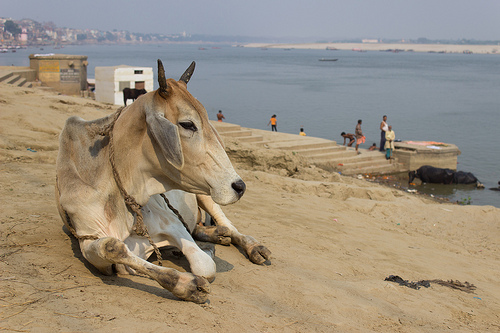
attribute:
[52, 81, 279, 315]
animal — laying, awake, lying down, lying, cow, tan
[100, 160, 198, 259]
rope — brown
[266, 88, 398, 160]
people — standing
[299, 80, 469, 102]
water — large body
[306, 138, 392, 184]
steps — stone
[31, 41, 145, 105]
group — buildings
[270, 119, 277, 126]
shirt — orange, pink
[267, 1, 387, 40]
sky — blue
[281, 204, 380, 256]
dirt — tan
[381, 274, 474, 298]
plant — dark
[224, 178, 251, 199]
nose — black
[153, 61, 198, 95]
horns — small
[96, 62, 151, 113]
structure — white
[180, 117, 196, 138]
eyes — open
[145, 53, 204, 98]
ears — large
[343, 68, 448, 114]
body — water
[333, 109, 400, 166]
group — men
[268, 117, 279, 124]
top — pink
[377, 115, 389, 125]
hair — brown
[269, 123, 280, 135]
pants — dark